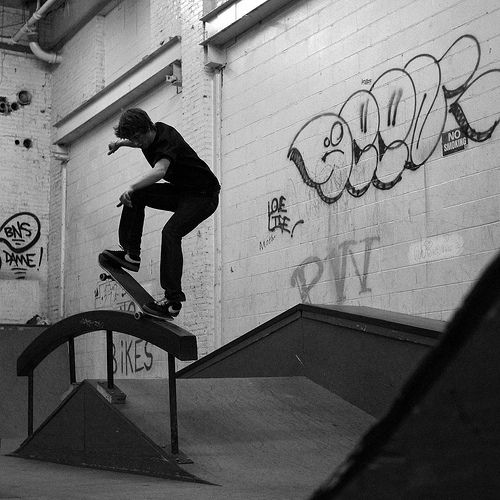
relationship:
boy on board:
[103, 108, 220, 321] [95, 246, 163, 329]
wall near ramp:
[36, 0, 500, 321] [0, 310, 476, 500]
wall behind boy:
[36, 0, 500, 321] [103, 108, 220, 321]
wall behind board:
[36, 0, 500, 321] [95, 246, 163, 329]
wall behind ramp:
[36, 0, 500, 321] [0, 310, 476, 500]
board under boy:
[95, 246, 163, 329] [103, 108, 220, 321]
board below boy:
[95, 246, 163, 329] [103, 108, 220, 321]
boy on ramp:
[103, 108, 220, 321] [0, 310, 476, 500]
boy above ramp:
[103, 108, 220, 321] [0, 310, 476, 500]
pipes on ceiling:
[5, 9, 67, 61] [6, 0, 289, 69]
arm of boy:
[122, 152, 172, 206] [103, 108, 220, 321]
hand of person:
[119, 192, 133, 208] [105, 102, 218, 315]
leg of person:
[158, 199, 190, 315] [105, 102, 218, 315]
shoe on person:
[151, 290, 184, 318] [105, 102, 218, 315]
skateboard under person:
[97, 250, 170, 321] [105, 102, 218, 315]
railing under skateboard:
[12, 310, 206, 380] [97, 250, 170, 321]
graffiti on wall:
[291, 33, 484, 222] [36, 0, 500, 321]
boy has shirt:
[103, 108, 220, 321] [137, 123, 226, 207]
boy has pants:
[110, 108, 220, 327] [118, 177, 222, 295]